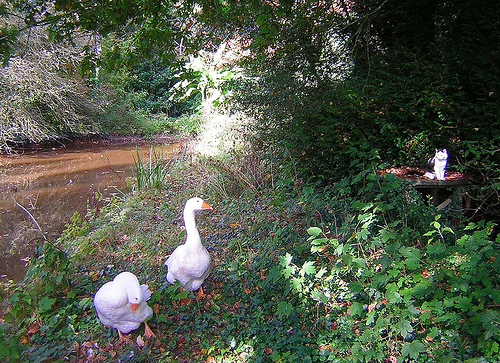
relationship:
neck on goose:
[183, 206, 203, 246] [166, 196, 214, 293]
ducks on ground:
[93, 271, 156, 342] [124, 164, 220, 263]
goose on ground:
[170, 197, 202, 299] [124, 164, 220, 263]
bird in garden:
[164, 197, 213, 299] [0, 117, 498, 358]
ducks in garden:
[93, 271, 156, 342] [0, 117, 498, 358]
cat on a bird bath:
[428, 132, 453, 176] [398, 161, 468, 212]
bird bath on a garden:
[405, 159, 467, 205] [0, 117, 498, 358]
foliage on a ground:
[269, 179, 499, 359] [0, 130, 498, 359]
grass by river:
[90, 130, 189, 201] [0, 134, 184, 300]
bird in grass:
[164, 197, 213, 299] [0, 140, 497, 358]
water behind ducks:
[67, 142, 135, 215] [72, 154, 252, 352]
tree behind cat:
[0, 0, 500, 195] [407, 147, 447, 180]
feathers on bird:
[159, 195, 214, 290] [162, 191, 217, 302]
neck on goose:
[178, 206, 205, 246] [163, 195, 213, 304]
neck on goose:
[112, 268, 141, 297] [93, 270, 154, 347]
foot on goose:
[140, 322, 159, 341] [95, 270, 158, 351]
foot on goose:
[111, 328, 131, 347] [95, 270, 158, 351]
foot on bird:
[196, 282, 209, 306] [164, 197, 213, 299]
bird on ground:
[164, 197, 213, 299] [0, 130, 498, 359]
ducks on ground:
[93, 271, 156, 342] [0, 130, 498, 359]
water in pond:
[67, 142, 135, 215] [0, 128, 270, 339]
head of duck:
[187, 193, 214, 215] [163, 192, 219, 301]